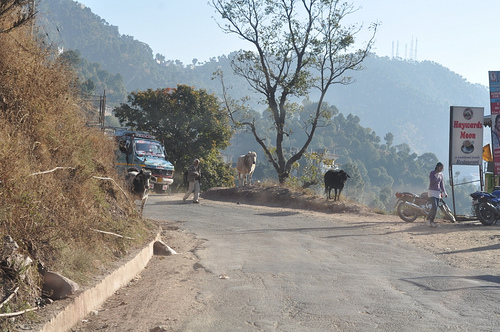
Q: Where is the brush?
A: Side of road.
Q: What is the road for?
A: Animal and vehicles to go down.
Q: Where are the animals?
A: Side of the road.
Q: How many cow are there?
A: Three.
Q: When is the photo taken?
A: Day time.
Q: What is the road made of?
A: Cement.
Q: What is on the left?
A: Grass.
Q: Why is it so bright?
A: Sunny.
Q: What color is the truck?
A: Blue.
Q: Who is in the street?
A: Pedestrians.